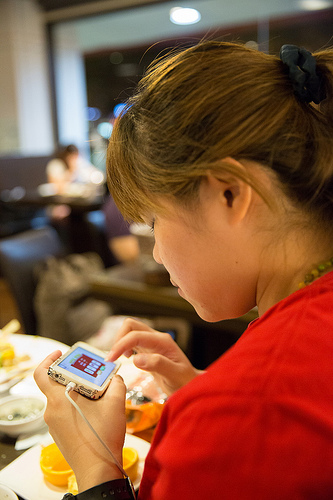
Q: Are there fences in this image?
A: No, there are no fences.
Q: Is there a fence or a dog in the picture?
A: No, there are no fences or dogs.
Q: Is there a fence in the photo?
A: No, there are no fences.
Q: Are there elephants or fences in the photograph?
A: No, there are no fences or elephants.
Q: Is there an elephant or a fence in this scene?
A: No, there are no fences or elephants.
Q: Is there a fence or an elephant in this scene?
A: No, there are no fences or elephants.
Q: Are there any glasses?
A: No, there are no glasses.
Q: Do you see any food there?
A: Yes, there is food.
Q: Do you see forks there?
A: No, there are no forks.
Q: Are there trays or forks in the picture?
A: No, there are no forks or trays.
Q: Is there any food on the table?
A: Yes, there is food on the table.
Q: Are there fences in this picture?
A: No, there are no fences.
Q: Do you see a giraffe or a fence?
A: No, there are no fences or giraffes.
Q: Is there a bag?
A: Yes, there is a bag.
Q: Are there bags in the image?
A: Yes, there is a bag.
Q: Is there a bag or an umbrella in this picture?
A: Yes, there is a bag.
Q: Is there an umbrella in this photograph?
A: No, there are no umbrellas.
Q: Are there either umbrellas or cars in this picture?
A: No, there are no umbrellas or cars.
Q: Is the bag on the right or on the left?
A: The bag is on the left of the image.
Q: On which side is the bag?
A: The bag is on the left of the image.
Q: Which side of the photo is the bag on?
A: The bag is on the left of the image.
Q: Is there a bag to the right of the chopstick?
A: Yes, there is a bag to the right of the chopstick.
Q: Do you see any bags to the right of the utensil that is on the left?
A: Yes, there is a bag to the right of the chopstick.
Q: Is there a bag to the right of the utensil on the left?
A: Yes, there is a bag to the right of the chopstick.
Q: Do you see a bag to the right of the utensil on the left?
A: Yes, there is a bag to the right of the chopstick.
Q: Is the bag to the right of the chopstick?
A: Yes, the bag is to the right of the chopstick.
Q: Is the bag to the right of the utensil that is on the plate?
A: Yes, the bag is to the right of the chopstick.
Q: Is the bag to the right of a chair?
A: No, the bag is to the right of the chopstick.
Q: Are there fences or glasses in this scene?
A: No, there are no glasses or fences.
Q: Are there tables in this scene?
A: Yes, there is a table.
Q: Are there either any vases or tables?
A: Yes, there is a table.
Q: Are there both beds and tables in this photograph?
A: No, there is a table but no beds.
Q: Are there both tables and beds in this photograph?
A: No, there is a table but no beds.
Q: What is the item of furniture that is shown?
A: The piece of furniture is a table.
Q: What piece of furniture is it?
A: The piece of furniture is a table.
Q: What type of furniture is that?
A: This is a table.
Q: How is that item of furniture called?
A: This is a table.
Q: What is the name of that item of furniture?
A: This is a table.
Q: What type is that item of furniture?
A: This is a table.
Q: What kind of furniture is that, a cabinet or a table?
A: This is a table.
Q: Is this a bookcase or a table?
A: This is a table.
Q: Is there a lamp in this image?
A: No, there are no lamps.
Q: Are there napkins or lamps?
A: No, there are no lamps or napkins.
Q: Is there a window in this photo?
A: Yes, there is a window.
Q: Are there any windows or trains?
A: Yes, there is a window.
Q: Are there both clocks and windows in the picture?
A: No, there is a window but no clocks.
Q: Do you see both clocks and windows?
A: No, there is a window but no clocks.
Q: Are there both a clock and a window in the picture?
A: No, there is a window but no clocks.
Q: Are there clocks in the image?
A: No, there are no clocks.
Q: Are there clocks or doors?
A: No, there are no clocks or doors.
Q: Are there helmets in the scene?
A: No, there are no helmets.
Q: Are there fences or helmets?
A: No, there are no helmets or fences.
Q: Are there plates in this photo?
A: Yes, there is a plate.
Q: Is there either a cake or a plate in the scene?
A: Yes, there is a plate.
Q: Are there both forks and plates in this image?
A: No, there is a plate but no forks.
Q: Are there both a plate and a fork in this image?
A: No, there is a plate but no forks.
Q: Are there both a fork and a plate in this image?
A: No, there is a plate but no forks.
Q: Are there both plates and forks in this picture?
A: No, there is a plate but no forks.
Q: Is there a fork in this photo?
A: No, there are no forks.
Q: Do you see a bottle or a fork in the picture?
A: No, there are no forks or bottles.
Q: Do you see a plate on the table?
A: Yes, there is a plate on the table.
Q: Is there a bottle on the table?
A: No, there is a plate on the table.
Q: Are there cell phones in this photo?
A: Yes, there is a cell phone.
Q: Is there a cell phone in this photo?
A: Yes, there is a cell phone.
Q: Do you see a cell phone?
A: Yes, there is a cell phone.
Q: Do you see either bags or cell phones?
A: Yes, there is a cell phone.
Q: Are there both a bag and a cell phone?
A: Yes, there are both a cell phone and a bag.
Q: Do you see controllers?
A: No, there are no controllers.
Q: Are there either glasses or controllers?
A: No, there are no controllers or glasses.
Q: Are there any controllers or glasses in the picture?
A: No, there are no controllers or glasses.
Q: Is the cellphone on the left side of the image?
A: Yes, the cellphone is on the left of the image.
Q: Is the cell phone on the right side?
A: No, the cell phone is on the left of the image.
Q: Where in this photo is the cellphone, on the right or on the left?
A: The cellphone is on the left of the image.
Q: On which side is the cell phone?
A: The cell phone is on the left of the image.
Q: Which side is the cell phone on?
A: The cell phone is on the left of the image.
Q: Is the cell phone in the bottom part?
A: Yes, the cell phone is in the bottom of the image.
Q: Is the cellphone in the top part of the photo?
A: No, the cellphone is in the bottom of the image.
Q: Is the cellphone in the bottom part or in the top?
A: The cellphone is in the bottom of the image.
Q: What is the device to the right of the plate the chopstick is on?
A: The device is a cell phone.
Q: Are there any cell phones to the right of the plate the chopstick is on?
A: Yes, there is a cell phone to the right of the plate.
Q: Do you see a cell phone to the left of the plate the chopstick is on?
A: No, the cell phone is to the right of the plate.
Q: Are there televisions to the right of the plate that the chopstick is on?
A: No, there is a cell phone to the right of the plate.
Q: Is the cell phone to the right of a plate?
A: Yes, the cell phone is to the right of a plate.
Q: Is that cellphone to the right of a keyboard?
A: No, the cellphone is to the right of a plate.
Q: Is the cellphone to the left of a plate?
A: No, the cellphone is to the right of a plate.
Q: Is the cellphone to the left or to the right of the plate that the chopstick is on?
A: The cellphone is to the right of the plate.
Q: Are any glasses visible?
A: No, there are no glasses.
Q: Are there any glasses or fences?
A: No, there are no glasses or fences.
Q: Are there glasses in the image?
A: No, there are no glasses.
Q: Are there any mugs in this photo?
A: No, there are no mugs.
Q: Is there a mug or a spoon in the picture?
A: No, there are no mugs or spoons.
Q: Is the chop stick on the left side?
A: Yes, the chop stick is on the left of the image.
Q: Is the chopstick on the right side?
A: No, the chopstick is on the left of the image.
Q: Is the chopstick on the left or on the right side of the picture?
A: The chopstick is on the left of the image.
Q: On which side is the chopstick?
A: The chopstick is on the left of the image.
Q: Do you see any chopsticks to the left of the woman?
A: Yes, there is a chopstick to the left of the woman.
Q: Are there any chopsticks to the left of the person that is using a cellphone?
A: Yes, there is a chopstick to the left of the woman.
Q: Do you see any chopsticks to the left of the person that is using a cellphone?
A: Yes, there is a chopstick to the left of the woman.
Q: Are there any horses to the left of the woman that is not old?
A: No, there is a chopstick to the left of the woman.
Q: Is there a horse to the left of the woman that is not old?
A: No, there is a chopstick to the left of the woman.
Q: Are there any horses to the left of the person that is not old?
A: No, there is a chopstick to the left of the woman.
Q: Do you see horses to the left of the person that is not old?
A: No, there is a chopstick to the left of the woman.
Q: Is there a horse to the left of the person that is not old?
A: No, there is a chopstick to the left of the woman.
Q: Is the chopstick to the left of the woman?
A: Yes, the chopstick is to the left of the woman.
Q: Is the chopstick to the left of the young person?
A: Yes, the chopstick is to the left of the woman.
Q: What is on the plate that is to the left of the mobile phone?
A: The chopstick is on the plate.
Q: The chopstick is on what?
A: The chopstick is on the plate.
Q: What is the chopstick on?
A: The chopstick is on the plate.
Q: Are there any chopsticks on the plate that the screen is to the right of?
A: Yes, there is a chopstick on the plate.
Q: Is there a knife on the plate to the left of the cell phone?
A: No, there is a chopstick on the plate.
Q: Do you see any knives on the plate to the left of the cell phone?
A: No, there is a chopstick on the plate.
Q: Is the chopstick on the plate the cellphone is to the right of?
A: Yes, the chopstick is on the plate.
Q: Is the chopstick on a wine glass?
A: No, the chopstick is on the plate.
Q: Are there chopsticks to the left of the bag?
A: Yes, there is a chopstick to the left of the bag.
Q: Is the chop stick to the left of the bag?
A: Yes, the chop stick is to the left of the bag.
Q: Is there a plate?
A: Yes, there is a plate.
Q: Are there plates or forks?
A: Yes, there is a plate.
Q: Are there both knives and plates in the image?
A: No, there is a plate but no knives.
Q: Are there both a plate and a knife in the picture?
A: No, there is a plate but no knives.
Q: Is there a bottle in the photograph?
A: No, there are no bottles.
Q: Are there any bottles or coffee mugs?
A: No, there are no bottles or coffee mugs.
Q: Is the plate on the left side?
A: Yes, the plate is on the left of the image.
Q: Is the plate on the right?
A: No, the plate is on the left of the image.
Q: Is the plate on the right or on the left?
A: The plate is on the left of the image.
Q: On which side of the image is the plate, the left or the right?
A: The plate is on the left of the image.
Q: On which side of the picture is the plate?
A: The plate is on the left of the image.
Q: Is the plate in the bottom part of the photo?
A: Yes, the plate is in the bottom of the image.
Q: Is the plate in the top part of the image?
A: No, the plate is in the bottom of the image.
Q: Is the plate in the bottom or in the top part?
A: The plate is in the bottom of the image.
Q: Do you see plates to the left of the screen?
A: Yes, there is a plate to the left of the screen.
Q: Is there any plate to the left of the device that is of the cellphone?
A: Yes, there is a plate to the left of the screen.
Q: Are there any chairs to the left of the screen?
A: No, there is a plate to the left of the screen.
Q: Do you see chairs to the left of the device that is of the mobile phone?
A: No, there is a plate to the left of the screen.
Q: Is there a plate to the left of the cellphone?
A: Yes, there is a plate to the left of the cellphone.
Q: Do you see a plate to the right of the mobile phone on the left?
A: No, the plate is to the left of the cellphone.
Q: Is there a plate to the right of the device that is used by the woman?
A: No, the plate is to the left of the cellphone.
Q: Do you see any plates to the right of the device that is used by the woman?
A: No, the plate is to the left of the cellphone.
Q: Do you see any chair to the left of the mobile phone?
A: No, there is a plate to the left of the mobile phone.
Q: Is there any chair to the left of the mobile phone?
A: No, there is a plate to the left of the mobile phone.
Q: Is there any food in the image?
A: Yes, there is food.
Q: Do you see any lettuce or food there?
A: Yes, there is food.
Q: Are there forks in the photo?
A: No, there are no forks.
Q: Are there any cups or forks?
A: No, there are no forks or cups.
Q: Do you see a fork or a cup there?
A: No, there are no forks or cups.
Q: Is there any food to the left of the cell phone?
A: Yes, there is food to the left of the cell phone.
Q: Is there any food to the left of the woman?
A: Yes, there is food to the left of the woman.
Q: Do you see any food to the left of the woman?
A: Yes, there is food to the left of the woman.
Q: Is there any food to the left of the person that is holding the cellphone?
A: Yes, there is food to the left of the woman.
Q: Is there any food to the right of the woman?
A: No, the food is to the left of the woman.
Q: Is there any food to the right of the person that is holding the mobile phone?
A: No, the food is to the left of the woman.